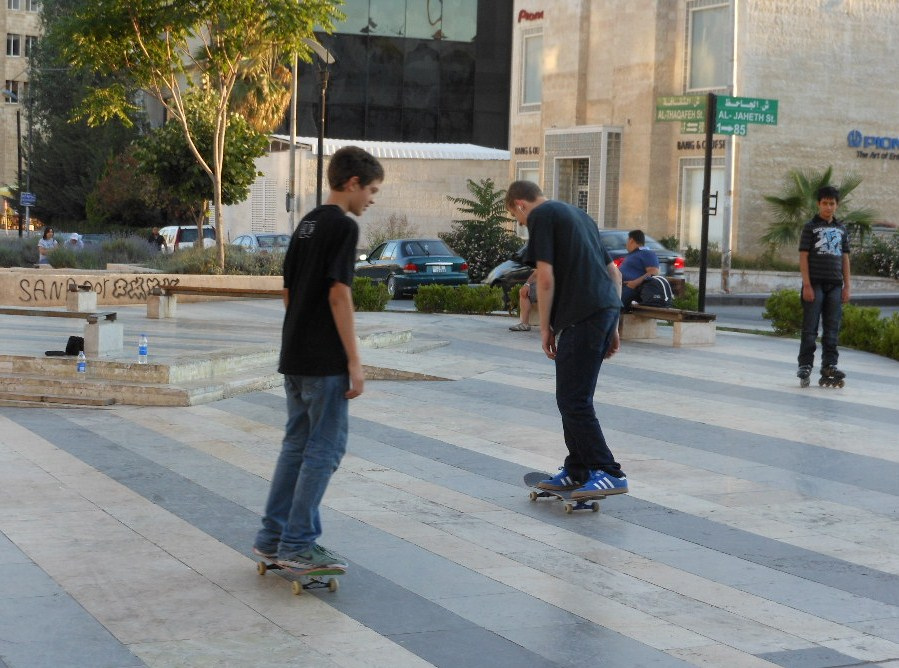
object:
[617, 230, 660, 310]
person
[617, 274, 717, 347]
bench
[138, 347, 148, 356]
label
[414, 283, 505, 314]
bushes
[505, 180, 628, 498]
boy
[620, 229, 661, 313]
boy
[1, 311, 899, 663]
ground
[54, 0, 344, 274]
tree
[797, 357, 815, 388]
rollerskate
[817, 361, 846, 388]
rollerskate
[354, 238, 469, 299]
vehicles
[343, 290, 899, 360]
road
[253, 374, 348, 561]
blue jeans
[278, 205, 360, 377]
shirt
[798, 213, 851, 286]
shirt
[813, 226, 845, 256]
print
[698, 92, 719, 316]
post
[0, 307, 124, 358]
bench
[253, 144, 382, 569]
boy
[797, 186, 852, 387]
boy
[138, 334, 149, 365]
water bottle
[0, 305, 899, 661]
area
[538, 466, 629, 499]
shoes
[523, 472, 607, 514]
skateboard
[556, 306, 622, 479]
jeans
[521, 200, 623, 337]
shirt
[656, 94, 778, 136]
lettering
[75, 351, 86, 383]
water bottle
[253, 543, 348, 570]
shoes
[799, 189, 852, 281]
top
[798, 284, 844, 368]
jeans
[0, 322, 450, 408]
steps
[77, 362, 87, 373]
labels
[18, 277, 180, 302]
graffiti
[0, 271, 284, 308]
wall